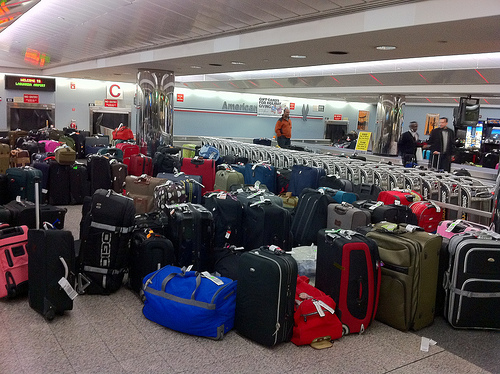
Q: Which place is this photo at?
A: It is at the airport.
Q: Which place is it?
A: It is an airport.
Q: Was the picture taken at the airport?
A: Yes, it was taken in the airport.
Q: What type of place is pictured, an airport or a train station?
A: It is an airport.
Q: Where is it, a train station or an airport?
A: It is an airport.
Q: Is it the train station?
A: No, it is the airport.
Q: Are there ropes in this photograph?
A: No, there are no ropes.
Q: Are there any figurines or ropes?
A: No, there are no ropes or figurines.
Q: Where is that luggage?
A: The luggage is at the airport.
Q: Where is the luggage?
A: The luggage is at the airport.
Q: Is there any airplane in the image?
A: No, there are no airplanes.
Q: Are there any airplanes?
A: No, there are no airplanes.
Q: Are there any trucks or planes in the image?
A: No, there are no planes or trucks.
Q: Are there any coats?
A: Yes, there is a coat.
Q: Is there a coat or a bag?
A: Yes, there is a coat.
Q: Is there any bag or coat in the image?
A: Yes, there is a coat.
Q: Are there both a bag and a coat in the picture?
A: Yes, there are both a coat and a bag.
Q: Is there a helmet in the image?
A: No, there are no helmets.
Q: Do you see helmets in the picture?
A: No, there are no helmets.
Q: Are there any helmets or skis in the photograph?
A: No, there are no helmets or skis.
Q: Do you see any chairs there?
A: No, there are no chairs.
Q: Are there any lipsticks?
A: No, there are no lipsticks.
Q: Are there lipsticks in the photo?
A: No, there are no lipsticks.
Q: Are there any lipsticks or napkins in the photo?
A: No, there are no lipsticks or napkins.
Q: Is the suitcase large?
A: Yes, the suitcase is large.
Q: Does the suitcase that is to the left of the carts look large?
A: Yes, the suitcase is large.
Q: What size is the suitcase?
A: The suitcase is large.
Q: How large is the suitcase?
A: The suitcase is large.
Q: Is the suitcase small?
A: No, the suitcase is large.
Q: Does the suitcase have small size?
A: No, the suitcase is large.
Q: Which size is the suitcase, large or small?
A: The suitcase is large.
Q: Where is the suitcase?
A: The suitcase is on the floor.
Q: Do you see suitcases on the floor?
A: Yes, there is a suitcase on the floor.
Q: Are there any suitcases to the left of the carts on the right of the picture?
A: Yes, there is a suitcase to the left of the carts.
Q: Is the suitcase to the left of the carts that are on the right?
A: Yes, the suitcase is to the left of the carts.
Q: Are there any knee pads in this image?
A: No, there are no knee pads.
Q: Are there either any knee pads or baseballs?
A: No, there are no knee pads or baseballs.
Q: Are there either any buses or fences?
A: No, there are no fences or buses.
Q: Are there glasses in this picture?
A: No, there are no glasses.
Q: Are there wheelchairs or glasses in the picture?
A: No, there are no glasses or wheelchairs.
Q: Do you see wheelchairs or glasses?
A: No, there are no glasses or wheelchairs.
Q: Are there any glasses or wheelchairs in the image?
A: No, there are no glasses or wheelchairs.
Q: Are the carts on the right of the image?
A: Yes, the carts are on the right of the image.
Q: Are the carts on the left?
A: No, the carts are on the right of the image.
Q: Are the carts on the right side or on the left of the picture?
A: The carts are on the right of the image.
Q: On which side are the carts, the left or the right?
A: The carts are on the right of the image.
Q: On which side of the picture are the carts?
A: The carts are on the right of the image.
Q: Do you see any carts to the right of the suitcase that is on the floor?
A: Yes, there are carts to the right of the suitcase.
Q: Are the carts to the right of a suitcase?
A: Yes, the carts are to the right of a suitcase.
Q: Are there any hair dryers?
A: No, there are no hair dryers.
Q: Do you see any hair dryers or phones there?
A: No, there are no hair dryers or phones.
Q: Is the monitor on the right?
A: Yes, the monitor is on the right of the image.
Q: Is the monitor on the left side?
A: No, the monitor is on the right of the image.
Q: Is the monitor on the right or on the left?
A: The monitor is on the right of the image.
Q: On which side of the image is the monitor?
A: The monitor is on the right of the image.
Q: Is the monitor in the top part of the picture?
A: Yes, the monitor is in the top of the image.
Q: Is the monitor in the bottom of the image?
A: No, the monitor is in the top of the image.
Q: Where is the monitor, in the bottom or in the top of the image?
A: The monitor is in the top of the image.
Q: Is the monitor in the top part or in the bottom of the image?
A: The monitor is in the top of the image.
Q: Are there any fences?
A: No, there are no fences.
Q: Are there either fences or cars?
A: No, there are no fences or cars.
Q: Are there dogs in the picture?
A: No, there are no dogs.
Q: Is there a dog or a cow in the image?
A: No, there are no dogs or cows.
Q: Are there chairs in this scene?
A: No, there are no chairs.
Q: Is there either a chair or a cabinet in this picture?
A: No, there are no chairs or cabinets.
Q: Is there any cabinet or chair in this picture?
A: No, there are no chairs or cabinets.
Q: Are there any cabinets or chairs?
A: No, there are no chairs or cabinets.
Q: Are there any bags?
A: Yes, there is a bag.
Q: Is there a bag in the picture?
A: Yes, there is a bag.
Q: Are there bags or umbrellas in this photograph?
A: Yes, there is a bag.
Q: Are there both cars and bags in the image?
A: No, there is a bag but no cars.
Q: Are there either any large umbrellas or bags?
A: Yes, there is a large bag.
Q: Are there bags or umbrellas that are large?
A: Yes, the bag is large.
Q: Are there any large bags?
A: Yes, there is a large bag.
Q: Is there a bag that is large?
A: Yes, there is a bag that is large.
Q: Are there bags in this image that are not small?
A: Yes, there is a large bag.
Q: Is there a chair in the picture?
A: No, there are no chairs.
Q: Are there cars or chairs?
A: No, there are no chairs or cars.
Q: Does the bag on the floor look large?
A: Yes, the bag is large.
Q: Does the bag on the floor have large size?
A: Yes, the bag is large.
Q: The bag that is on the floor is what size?
A: The bag is large.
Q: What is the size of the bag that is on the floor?
A: The bag is large.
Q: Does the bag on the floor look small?
A: No, the bag is large.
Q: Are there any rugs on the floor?
A: No, there is a bag on the floor.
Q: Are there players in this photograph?
A: No, there are no players.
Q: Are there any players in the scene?
A: No, there are no players.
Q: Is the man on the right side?
A: Yes, the man is on the right of the image.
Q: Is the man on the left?
A: No, the man is on the right of the image.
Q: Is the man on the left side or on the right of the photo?
A: The man is on the right of the image.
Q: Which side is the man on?
A: The man is on the right of the image.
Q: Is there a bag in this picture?
A: Yes, there is a bag.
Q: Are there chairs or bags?
A: Yes, there is a bag.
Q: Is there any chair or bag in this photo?
A: Yes, there is a bag.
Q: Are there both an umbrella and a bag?
A: No, there is a bag but no umbrellas.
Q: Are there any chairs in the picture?
A: No, there are no chairs.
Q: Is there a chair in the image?
A: No, there are no chairs.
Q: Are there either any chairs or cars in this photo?
A: No, there are no chairs or cars.